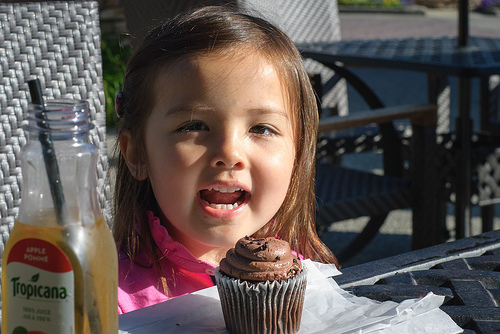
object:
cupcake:
[214, 234, 308, 333]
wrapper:
[215, 272, 306, 332]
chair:
[0, 0, 115, 264]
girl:
[108, 7, 336, 311]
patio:
[0, 0, 500, 334]